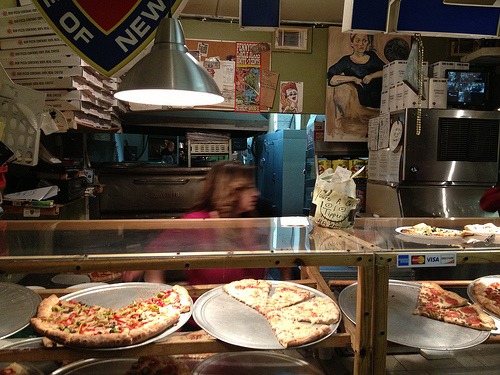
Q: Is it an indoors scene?
A: Yes, it is indoors.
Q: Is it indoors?
A: Yes, it is indoors.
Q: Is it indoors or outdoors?
A: It is indoors.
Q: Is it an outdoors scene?
A: No, it is indoors.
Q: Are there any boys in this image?
A: No, there are no boys.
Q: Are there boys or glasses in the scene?
A: No, there are no boys or glasses.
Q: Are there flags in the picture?
A: No, there are no flags.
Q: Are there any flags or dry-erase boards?
A: No, there are no flags or dry-erase boards.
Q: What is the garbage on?
A: The garbage is on the counter.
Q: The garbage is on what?
A: The garbage is on the counter.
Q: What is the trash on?
A: The garbage is on the counter.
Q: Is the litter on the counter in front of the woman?
A: Yes, the litter is on the counter.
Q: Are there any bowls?
A: No, there are no bowls.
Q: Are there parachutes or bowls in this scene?
A: No, there are no bowls or parachutes.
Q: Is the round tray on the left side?
A: Yes, the tray is on the left of the image.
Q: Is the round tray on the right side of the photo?
A: No, the tray is on the left of the image.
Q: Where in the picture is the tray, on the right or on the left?
A: The tray is on the left of the image.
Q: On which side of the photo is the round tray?
A: The tray is on the left of the image.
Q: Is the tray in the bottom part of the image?
A: Yes, the tray is in the bottom of the image.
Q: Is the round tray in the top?
A: No, the tray is in the bottom of the image.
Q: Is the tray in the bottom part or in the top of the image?
A: The tray is in the bottom of the image.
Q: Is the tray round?
A: Yes, the tray is round.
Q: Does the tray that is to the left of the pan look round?
A: Yes, the tray is round.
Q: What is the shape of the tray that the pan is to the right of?
A: The tray is round.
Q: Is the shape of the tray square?
A: No, the tray is round.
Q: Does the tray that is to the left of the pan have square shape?
A: No, the tray is round.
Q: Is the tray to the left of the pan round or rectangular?
A: The tray is round.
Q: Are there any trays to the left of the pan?
A: Yes, there is a tray to the left of the pan.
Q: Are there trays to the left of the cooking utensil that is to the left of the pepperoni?
A: Yes, there is a tray to the left of the pan.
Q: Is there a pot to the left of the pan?
A: No, there is a tray to the left of the pan.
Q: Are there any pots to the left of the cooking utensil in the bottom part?
A: No, there is a tray to the left of the pan.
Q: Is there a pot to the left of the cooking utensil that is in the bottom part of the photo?
A: No, there is a tray to the left of the pan.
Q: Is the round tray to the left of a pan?
A: Yes, the tray is to the left of a pan.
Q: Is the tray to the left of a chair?
A: No, the tray is to the left of a pan.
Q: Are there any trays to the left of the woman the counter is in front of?
A: Yes, there is a tray to the left of the woman.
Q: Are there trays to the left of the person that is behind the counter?
A: Yes, there is a tray to the left of the woman.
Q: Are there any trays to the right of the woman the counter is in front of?
A: No, the tray is to the left of the woman.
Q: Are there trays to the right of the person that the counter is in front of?
A: No, the tray is to the left of the woman.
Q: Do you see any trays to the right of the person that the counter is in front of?
A: No, the tray is to the left of the woman.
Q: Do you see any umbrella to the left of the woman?
A: No, there is a tray to the left of the woman.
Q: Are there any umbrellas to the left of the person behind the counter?
A: No, there is a tray to the left of the woman.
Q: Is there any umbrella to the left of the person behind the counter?
A: No, there is a tray to the left of the woman.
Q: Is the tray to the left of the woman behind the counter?
A: Yes, the tray is to the left of the woman.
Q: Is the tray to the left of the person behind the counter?
A: Yes, the tray is to the left of the woman.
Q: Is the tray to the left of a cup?
A: No, the tray is to the left of the woman.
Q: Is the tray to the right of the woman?
A: No, the tray is to the left of the woman.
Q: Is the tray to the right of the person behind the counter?
A: No, the tray is to the left of the woman.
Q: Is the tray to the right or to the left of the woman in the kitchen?
A: The tray is to the left of the woman.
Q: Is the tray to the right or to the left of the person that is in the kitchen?
A: The tray is to the left of the woman.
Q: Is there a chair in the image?
A: No, there are no chairs.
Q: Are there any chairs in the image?
A: No, there are no chairs.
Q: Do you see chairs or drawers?
A: No, there are no chairs or drawers.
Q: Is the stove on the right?
A: Yes, the stove is on the right of the image.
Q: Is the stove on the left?
A: No, the stove is on the right of the image.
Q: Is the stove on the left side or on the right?
A: The stove is on the right of the image.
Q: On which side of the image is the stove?
A: The stove is on the right of the image.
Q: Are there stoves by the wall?
A: Yes, there is a stove by the wall.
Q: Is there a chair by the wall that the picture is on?
A: No, there is a stove by the wall.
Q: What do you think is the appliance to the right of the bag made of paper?
A: The appliance is a stove.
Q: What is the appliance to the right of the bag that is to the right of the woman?
A: The appliance is a stove.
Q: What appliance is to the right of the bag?
A: The appliance is a stove.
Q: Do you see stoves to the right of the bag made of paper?
A: Yes, there is a stove to the right of the bag.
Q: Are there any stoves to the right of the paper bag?
A: Yes, there is a stove to the right of the bag.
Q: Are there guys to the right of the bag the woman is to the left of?
A: No, there is a stove to the right of the bag.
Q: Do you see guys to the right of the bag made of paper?
A: No, there is a stove to the right of the bag.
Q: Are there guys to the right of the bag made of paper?
A: No, there is a stove to the right of the bag.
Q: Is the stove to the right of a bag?
A: Yes, the stove is to the right of a bag.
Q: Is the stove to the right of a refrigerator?
A: No, the stove is to the right of a bag.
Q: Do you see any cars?
A: No, there are no cars.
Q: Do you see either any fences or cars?
A: No, there are no cars or fences.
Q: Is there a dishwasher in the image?
A: No, there are no dishwashers.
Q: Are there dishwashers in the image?
A: No, there are no dishwashers.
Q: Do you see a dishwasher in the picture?
A: No, there are no dishwashers.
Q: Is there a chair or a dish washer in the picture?
A: No, there are no dishwashers or chairs.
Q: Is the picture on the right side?
A: Yes, the picture is on the right of the image.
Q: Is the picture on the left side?
A: No, the picture is on the right of the image.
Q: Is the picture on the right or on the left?
A: The picture is on the right of the image.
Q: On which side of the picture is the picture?
A: The picture is on the right of the image.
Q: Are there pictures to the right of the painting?
A: Yes, there is a picture to the right of the painting.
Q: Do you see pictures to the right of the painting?
A: Yes, there is a picture to the right of the painting.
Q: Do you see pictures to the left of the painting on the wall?
A: No, the picture is to the right of the painting.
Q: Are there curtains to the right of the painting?
A: No, there is a picture to the right of the painting.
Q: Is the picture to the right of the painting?
A: Yes, the picture is to the right of the painting.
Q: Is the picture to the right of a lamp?
A: No, the picture is to the right of the painting.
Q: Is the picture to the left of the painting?
A: No, the picture is to the right of the painting.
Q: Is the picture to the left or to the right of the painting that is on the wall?
A: The picture is to the right of the painting.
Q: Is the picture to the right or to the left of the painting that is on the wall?
A: The picture is to the right of the painting.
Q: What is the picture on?
A: The picture is on the wall.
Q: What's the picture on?
A: The picture is on the wall.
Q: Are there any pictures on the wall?
A: Yes, there is a picture on the wall.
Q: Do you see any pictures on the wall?
A: Yes, there is a picture on the wall.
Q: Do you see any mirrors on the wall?
A: No, there is a picture on the wall.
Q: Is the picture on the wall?
A: Yes, the picture is on the wall.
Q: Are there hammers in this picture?
A: No, there are no hammers.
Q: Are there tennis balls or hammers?
A: No, there are no hammers or tennis balls.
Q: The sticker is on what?
A: The sticker is on the counter.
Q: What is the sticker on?
A: The sticker is on the counter.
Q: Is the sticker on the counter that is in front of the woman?
A: Yes, the sticker is on the counter.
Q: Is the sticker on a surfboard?
A: No, the sticker is on the counter.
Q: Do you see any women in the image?
A: Yes, there is a woman.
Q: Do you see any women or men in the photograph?
A: Yes, there is a woman.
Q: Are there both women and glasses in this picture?
A: No, there is a woman but no glasses.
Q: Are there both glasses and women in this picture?
A: No, there is a woman but no glasses.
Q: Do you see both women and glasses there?
A: No, there is a woman but no glasses.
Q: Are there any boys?
A: No, there are no boys.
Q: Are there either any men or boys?
A: No, there are no boys or men.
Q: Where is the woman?
A: The woman is in the kitchen.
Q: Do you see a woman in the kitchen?
A: Yes, there is a woman in the kitchen.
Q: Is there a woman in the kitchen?
A: Yes, there is a woman in the kitchen.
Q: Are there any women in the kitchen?
A: Yes, there is a woman in the kitchen.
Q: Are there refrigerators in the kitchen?
A: No, there is a woman in the kitchen.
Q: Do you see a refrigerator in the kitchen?
A: No, there is a woman in the kitchen.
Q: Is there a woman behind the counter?
A: Yes, there is a woman behind the counter.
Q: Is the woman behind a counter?
A: Yes, the woman is behind a counter.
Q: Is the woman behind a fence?
A: No, the woman is behind a counter.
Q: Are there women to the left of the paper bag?
A: Yes, there is a woman to the left of the bag.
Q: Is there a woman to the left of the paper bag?
A: Yes, there is a woman to the left of the bag.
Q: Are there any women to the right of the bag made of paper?
A: No, the woman is to the left of the bag.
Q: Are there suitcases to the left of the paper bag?
A: No, there is a woman to the left of the bag.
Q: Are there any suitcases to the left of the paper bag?
A: No, there is a woman to the left of the bag.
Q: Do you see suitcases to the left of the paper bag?
A: No, there is a woman to the left of the bag.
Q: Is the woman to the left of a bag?
A: Yes, the woman is to the left of a bag.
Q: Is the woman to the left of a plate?
A: No, the woman is to the left of a bag.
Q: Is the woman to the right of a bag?
A: No, the woman is to the left of a bag.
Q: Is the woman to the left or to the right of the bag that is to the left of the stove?
A: The woman is to the left of the bag.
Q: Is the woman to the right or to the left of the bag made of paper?
A: The woman is to the left of the bag.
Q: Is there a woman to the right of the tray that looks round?
A: Yes, there is a woman to the right of the tray.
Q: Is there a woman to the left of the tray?
A: No, the woman is to the right of the tray.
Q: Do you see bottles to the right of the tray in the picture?
A: No, there is a woman to the right of the tray.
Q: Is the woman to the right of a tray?
A: Yes, the woman is to the right of a tray.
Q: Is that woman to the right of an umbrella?
A: No, the woman is to the right of a tray.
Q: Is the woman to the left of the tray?
A: No, the woman is to the right of the tray.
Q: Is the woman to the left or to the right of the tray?
A: The woman is to the right of the tray.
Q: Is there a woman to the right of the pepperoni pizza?
A: Yes, there is a woman to the right of the pizza.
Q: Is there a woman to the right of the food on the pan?
A: Yes, there is a woman to the right of the pizza.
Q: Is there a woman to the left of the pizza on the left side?
A: No, the woman is to the right of the pizza.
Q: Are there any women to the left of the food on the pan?
A: No, the woman is to the right of the pizza.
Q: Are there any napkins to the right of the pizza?
A: No, there is a woman to the right of the pizza.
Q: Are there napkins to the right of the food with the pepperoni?
A: No, there is a woman to the right of the pizza.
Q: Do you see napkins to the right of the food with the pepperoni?
A: No, there is a woman to the right of the pizza.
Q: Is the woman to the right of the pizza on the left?
A: Yes, the woman is to the right of the pizza.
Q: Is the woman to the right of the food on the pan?
A: Yes, the woman is to the right of the pizza.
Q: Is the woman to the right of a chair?
A: No, the woman is to the right of the pizza.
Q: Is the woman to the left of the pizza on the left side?
A: No, the woman is to the right of the pizza.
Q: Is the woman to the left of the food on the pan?
A: No, the woman is to the right of the pizza.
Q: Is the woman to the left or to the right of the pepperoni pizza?
A: The woman is to the right of the pizza.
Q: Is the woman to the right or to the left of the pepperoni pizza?
A: The woman is to the right of the pizza.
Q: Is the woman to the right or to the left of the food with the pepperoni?
A: The woman is to the right of the pizza.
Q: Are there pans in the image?
A: Yes, there is a pan.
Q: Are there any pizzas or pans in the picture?
A: Yes, there is a pan.